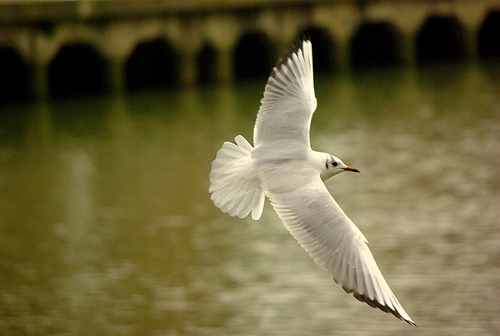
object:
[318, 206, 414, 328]
feathers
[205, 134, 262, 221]
tail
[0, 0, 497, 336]
sky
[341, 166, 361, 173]
beak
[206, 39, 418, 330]
bird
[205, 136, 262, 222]
feathers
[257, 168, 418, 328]
wing